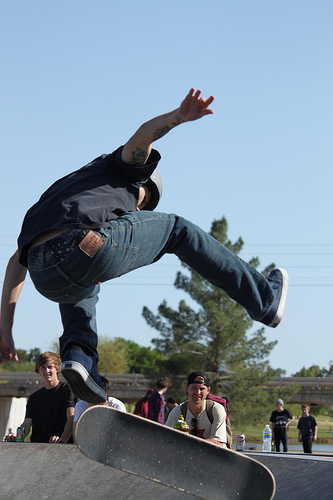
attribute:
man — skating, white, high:
[20, 126, 291, 383]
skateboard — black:
[78, 406, 259, 498]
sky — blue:
[44, 10, 123, 69]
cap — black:
[148, 176, 169, 193]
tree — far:
[173, 294, 244, 370]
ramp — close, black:
[21, 449, 74, 490]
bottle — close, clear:
[256, 423, 279, 453]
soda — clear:
[238, 427, 254, 451]